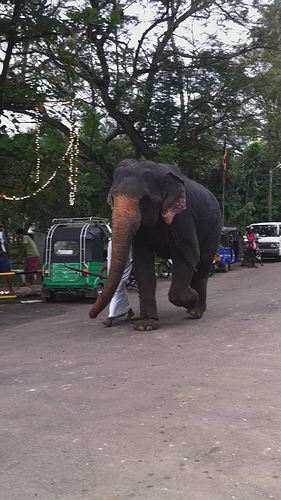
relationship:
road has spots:
[0, 262, 279, 499] [141, 407, 220, 490]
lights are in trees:
[0, 106, 81, 207] [0, 0, 279, 225]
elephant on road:
[88, 160, 222, 333] [0, 262, 279, 499]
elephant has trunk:
[88, 160, 222, 333] [87, 195, 143, 320]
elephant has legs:
[88, 160, 222, 333] [131, 249, 213, 333]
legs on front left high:
[131, 249, 213, 333] [168, 258, 200, 308]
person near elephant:
[107, 224, 131, 321] [88, 160, 222, 333]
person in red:
[242, 227, 255, 270] [243, 234, 254, 250]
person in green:
[15, 229, 40, 284] [19, 234, 35, 255]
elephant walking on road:
[88, 160, 222, 333] [0, 262, 279, 499]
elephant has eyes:
[88, 160, 222, 333] [110, 195, 154, 205]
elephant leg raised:
[88, 160, 222, 333] [168, 258, 200, 308]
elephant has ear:
[88, 160, 222, 333] [163, 173, 188, 224]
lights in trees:
[0, 106, 81, 207] [0, 0, 279, 225]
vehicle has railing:
[209, 230, 234, 272] [45, 217, 91, 277]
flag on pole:
[221, 141, 226, 182] [221, 180, 226, 234]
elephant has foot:
[88, 160, 222, 333] [132, 318, 158, 330]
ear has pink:
[163, 173, 188, 224] [163, 186, 188, 222]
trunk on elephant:
[87, 195, 143, 320] [88, 160, 222, 333]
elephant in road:
[88, 160, 222, 333] [0, 262, 279, 499]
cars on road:
[44, 219, 133, 296] [0, 262, 279, 499]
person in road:
[107, 224, 131, 321] [0, 262, 279, 499]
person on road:
[107, 224, 131, 321] [0, 262, 279, 499]